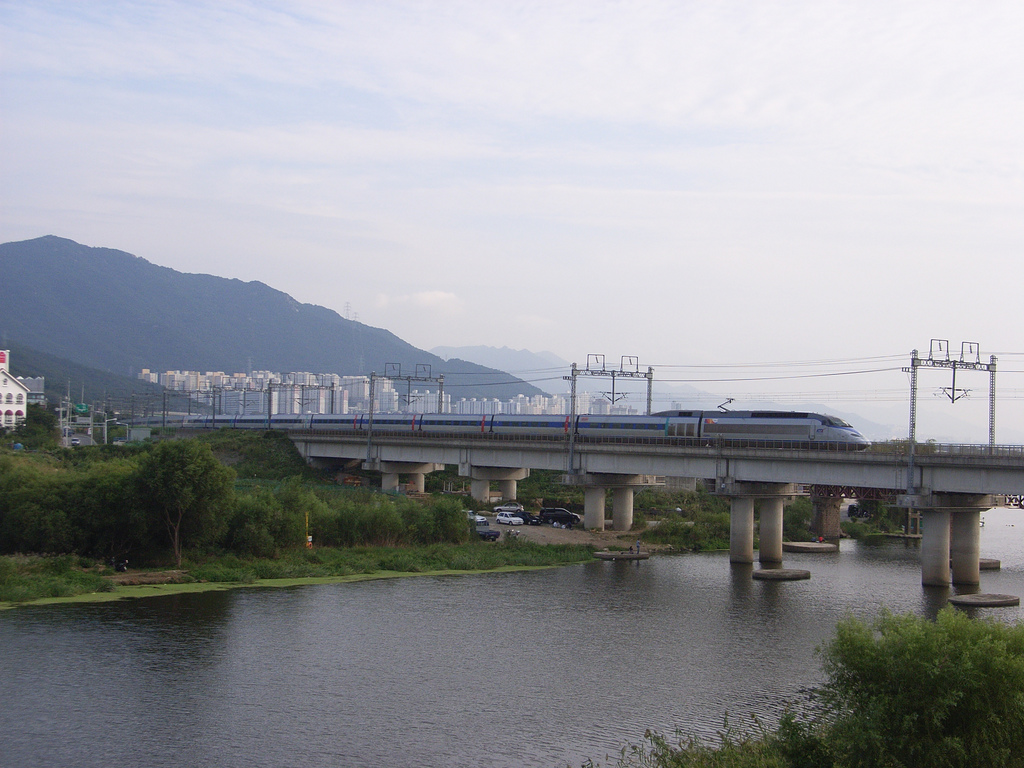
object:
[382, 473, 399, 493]
pillar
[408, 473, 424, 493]
pillar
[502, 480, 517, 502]
pillar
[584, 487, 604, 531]
pillar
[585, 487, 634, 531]
pillar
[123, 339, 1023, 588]
bridge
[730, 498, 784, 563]
pillar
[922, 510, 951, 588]
pillar